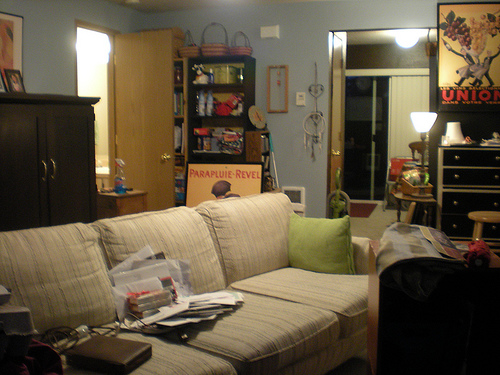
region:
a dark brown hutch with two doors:
[0, 90, 102, 232]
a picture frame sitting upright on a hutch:
[2, 65, 27, 96]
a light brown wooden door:
[72, 18, 177, 214]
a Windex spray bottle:
[112, 156, 128, 198]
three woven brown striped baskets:
[177, 21, 254, 62]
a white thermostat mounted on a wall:
[294, 89, 307, 109]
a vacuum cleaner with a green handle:
[323, 166, 353, 225]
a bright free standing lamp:
[409, 108, 439, 179]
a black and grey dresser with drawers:
[432, 143, 498, 244]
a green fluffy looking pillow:
[284, 208, 358, 277]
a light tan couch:
[4, 191, 376, 369]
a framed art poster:
[435, 2, 499, 116]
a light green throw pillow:
[282, 208, 355, 275]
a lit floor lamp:
[404, 107, 434, 174]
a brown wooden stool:
[465, 208, 499, 245]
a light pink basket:
[199, 18, 229, 56]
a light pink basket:
[229, 28, 250, 55]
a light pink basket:
[180, 30, 200, 56]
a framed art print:
[184, 159, 264, 208]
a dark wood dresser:
[0, 92, 102, 231]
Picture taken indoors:
[13, 8, 498, 370]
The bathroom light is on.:
[78, 36, 97, 75]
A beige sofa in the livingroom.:
[41, 242, 358, 349]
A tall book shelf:
[191, 68, 247, 151]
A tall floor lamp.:
[410, 100, 433, 215]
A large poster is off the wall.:
[187, 163, 264, 188]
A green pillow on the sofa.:
[290, 216, 345, 268]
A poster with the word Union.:
[446, 12, 488, 102]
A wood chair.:
[474, 210, 496, 222]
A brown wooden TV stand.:
[22, 108, 94, 207]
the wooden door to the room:
[113, 28, 175, 215]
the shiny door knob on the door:
[161, 153, 169, 161]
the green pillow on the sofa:
[288, 213, 353, 274]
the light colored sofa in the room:
[4, 192, 368, 373]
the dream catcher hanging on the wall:
[301, 63, 325, 163]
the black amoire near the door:
[0, 91, 100, 221]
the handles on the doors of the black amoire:
[40, 158, 57, 181]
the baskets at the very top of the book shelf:
[181, 22, 253, 56]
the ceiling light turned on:
[394, 32, 418, 47]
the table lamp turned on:
[410, 111, 436, 199]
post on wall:
[436, 0, 498, 110]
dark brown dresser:
[0, 92, 99, 228]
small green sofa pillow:
[289, 210, 354, 275]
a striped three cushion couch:
[1, 190, 372, 366]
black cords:
[38, 311, 126, 348]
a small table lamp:
[410, 109, 430, 196]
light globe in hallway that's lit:
[386, 29, 422, 49]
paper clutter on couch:
[96, 244, 245, 339]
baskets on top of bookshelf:
[175, 23, 249, 53]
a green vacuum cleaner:
[325, 168, 348, 216]